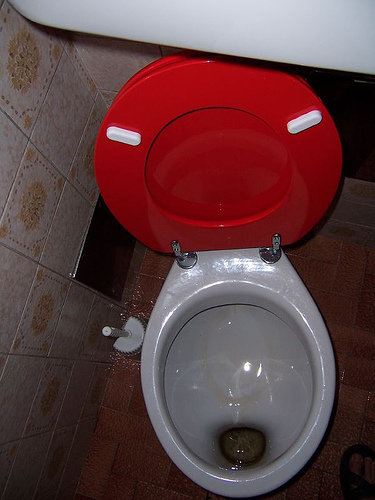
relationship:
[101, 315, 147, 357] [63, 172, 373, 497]
brush on ground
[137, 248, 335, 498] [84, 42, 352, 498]
bowl on toilet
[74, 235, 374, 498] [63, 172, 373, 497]
tiles on ground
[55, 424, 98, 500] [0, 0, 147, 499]
tile on wall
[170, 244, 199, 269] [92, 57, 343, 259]
hinge on toilet seat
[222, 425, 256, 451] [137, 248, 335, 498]
water in bowl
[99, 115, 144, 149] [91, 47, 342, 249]
white stopper on lid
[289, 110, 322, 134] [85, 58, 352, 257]
stopper on lid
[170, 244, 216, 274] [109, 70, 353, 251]
hinge on toilet lid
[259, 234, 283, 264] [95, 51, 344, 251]
hinge on lid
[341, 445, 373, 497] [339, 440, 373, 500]
foot on floor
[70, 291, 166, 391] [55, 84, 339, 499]
brush beside toilet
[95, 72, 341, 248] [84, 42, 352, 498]
lid on toilet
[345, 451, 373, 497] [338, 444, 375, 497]
foot with sandals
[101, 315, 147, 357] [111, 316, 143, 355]
brush in holder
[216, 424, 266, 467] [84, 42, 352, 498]
hole in toilet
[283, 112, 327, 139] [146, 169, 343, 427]
piece on toilet